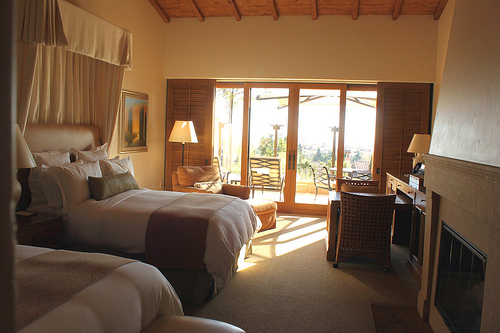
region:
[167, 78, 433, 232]
window on lving room wall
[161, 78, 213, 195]
shutter bordering window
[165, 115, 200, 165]
floor length lamp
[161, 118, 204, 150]
white lamp shade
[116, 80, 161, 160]
framed painting on wall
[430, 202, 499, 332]
square vent on wall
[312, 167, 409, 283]
table and wicker chairs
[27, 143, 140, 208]
throw pillows at head of bed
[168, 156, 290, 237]
tan lounge chair in front of window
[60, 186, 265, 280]
brown and white comforter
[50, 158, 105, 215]
a white pillow on a bed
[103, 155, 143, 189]
a white pillow on a bed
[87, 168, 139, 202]
a small pillow on a bed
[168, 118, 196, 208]
a lamp by the corner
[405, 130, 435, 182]
a lamp by the corner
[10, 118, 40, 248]
a lamp by the bed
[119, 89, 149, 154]
a painting on the wall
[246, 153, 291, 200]
a small brown chair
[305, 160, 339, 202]
a small black chair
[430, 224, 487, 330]
opening for a fireplace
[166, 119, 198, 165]
floor lamp with white shade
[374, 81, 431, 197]
wooden panel over window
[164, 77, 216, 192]
wooden panel over window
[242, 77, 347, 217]
two glass doors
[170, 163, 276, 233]
chair sitting in hotel room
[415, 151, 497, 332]
mantle around fireplace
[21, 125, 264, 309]
bed made with pillows and blankets in hotel room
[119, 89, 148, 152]
framed painting on the wall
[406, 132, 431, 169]
lamp with a white shade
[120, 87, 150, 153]
a picture on the wall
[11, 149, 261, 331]
two beds with brown and white cover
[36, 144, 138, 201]
four white pillows and one long brown pillow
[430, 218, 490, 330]
a black air vent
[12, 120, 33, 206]
a lamp with a white shade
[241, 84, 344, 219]
two glass doors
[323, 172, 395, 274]
a table and two chairs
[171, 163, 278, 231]
a tan chair and ottoman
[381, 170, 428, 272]
a brown wooden desk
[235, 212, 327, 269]
light shining on the floor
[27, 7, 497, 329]
Photo of bedroom interior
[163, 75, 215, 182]
Slated wooden door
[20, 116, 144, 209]
Pillows stacked against headboard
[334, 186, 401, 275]
Brown wooden chair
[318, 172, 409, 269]
Two chairs and a table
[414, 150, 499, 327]
Fireplace grate and mantle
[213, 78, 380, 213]
Sliding doors and windows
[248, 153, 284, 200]
Deck chair seen outside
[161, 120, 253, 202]
Floor lamp and recliner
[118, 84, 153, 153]
Desert landscape painting hanging from wall